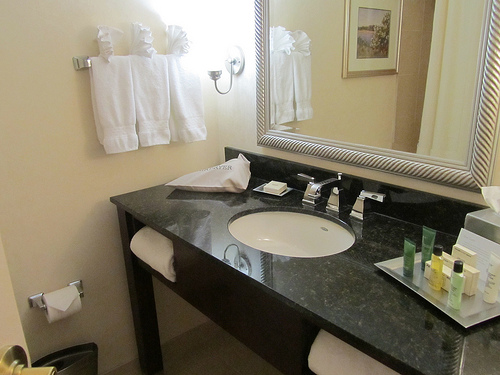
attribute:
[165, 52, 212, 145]
towel — white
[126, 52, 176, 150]
towel — white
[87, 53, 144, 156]
towel — white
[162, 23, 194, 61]
towel — white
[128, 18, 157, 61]
towel — white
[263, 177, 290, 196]
soap — bar, white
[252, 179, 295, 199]
dish — square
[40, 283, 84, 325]
toilet paper — folded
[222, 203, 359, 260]
sink — round, white, oval